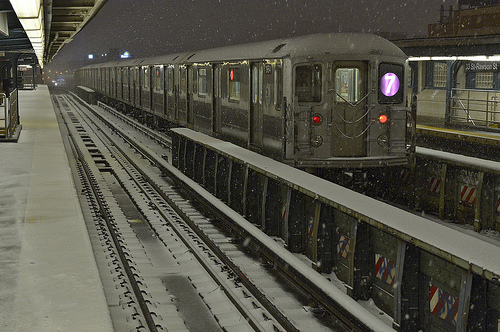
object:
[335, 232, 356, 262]
sign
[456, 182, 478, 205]
sign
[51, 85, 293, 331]
track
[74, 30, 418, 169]
train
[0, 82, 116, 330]
platform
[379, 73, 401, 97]
circle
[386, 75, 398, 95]
number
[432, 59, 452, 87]
window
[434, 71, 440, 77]
block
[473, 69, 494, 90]
window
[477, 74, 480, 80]
block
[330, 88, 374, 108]
rope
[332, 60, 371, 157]
door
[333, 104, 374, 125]
rope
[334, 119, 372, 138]
rope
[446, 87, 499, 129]
railing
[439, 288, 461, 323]
graffiti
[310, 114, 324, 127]
light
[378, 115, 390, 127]
light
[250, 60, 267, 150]
door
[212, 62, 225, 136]
door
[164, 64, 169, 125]
door